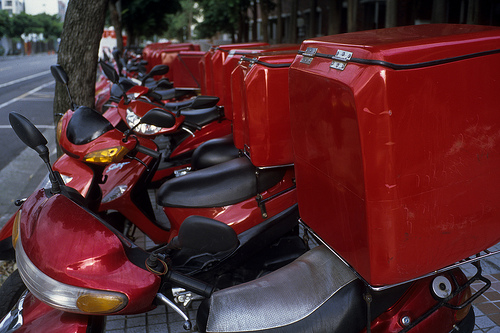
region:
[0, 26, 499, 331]
The mopeds all have boxes on the back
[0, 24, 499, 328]
All the mopeds are red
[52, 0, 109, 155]
The tree is left of the scooters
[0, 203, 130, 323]
The closest moped has three sections in its headlight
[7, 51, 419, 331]
All the mopeds have black seats and handlebars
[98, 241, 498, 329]
The sidewalk is brick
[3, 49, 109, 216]
The street is empty and grey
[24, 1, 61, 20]
The sky is overcast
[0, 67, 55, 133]
White lines are painted on the street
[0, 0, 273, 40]
The leaves are green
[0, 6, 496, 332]
delivery motorbikes parked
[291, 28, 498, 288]
the luggage box is red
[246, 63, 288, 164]
the luggage box is red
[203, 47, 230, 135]
the luggage box is red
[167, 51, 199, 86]
the luggage box is red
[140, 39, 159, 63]
the luggage box is red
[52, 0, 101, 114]
the trunk of a tree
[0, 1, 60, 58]
trees in the background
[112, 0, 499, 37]
trees in the background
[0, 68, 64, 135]
white lines on the road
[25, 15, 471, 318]
motorbikes parked side by side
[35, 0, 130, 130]
curved tree trunk in front of bikes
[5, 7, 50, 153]
road in front of parked bikes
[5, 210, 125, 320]
wide white headlight with smaller yellow lights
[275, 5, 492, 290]
storage box on back of motorbike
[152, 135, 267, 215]
long and narrow black seat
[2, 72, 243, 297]
black handlebar on top of metal casing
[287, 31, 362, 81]
hinges connecting box to lid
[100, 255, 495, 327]
pavement of small tan and white tiles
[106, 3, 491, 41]
trees and buildings near the motorbikes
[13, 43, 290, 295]
row of red bikes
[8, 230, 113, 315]
light on front of bike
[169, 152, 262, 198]
black seat on bike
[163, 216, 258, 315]
black handle on bike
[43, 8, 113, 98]
tree next to bikes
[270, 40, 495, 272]
red box on back of bike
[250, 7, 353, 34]
building behind the bikes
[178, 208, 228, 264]
mirror on the bike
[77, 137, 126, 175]
orange part of the bike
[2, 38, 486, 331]
line of red motorcycles parked on sidewalk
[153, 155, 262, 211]
black motorcycle seat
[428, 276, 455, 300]
silver gas tank cover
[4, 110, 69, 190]
black rear view mirror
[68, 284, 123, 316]
orange headlight on front of motorcycle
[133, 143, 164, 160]
black motorcycle handlebar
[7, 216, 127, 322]
headlights on front of motorcycle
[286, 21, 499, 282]
red metal cargo carrier for back of motorcycle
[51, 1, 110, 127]
brown tree trunk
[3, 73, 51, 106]
white lines drawn on street